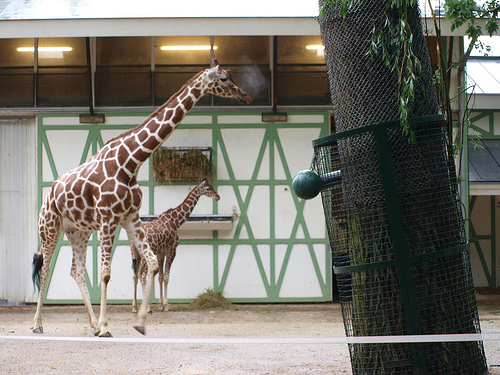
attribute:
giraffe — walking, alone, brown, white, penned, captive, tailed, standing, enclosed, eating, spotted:
[20, 44, 259, 342]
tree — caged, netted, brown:
[309, 2, 475, 320]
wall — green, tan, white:
[35, 115, 346, 300]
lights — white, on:
[16, 36, 327, 69]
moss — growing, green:
[343, 6, 435, 132]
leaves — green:
[332, 1, 499, 140]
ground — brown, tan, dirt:
[3, 300, 500, 374]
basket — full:
[153, 143, 213, 189]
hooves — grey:
[29, 320, 153, 343]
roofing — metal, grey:
[461, 133, 499, 191]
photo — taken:
[0, 3, 499, 330]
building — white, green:
[1, 2, 497, 325]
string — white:
[3, 331, 500, 349]